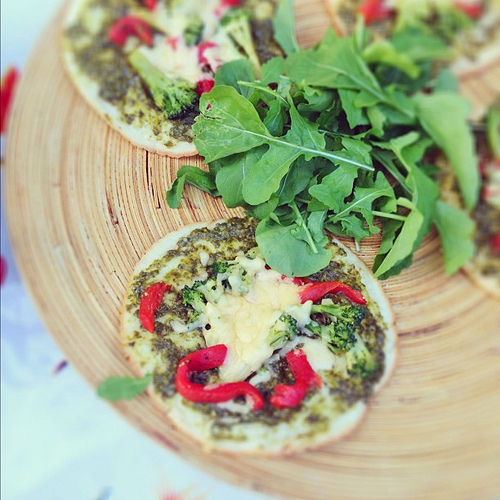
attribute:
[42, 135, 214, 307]
plate — wooden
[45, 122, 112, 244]
line — curved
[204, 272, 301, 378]
cheese — cluster, melted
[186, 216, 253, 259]
broccoli — tiny, crown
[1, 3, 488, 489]
plate — wicker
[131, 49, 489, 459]
food — colorful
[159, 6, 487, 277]
greens — handful, leafy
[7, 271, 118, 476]
table — white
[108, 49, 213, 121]
broccoli — green, peice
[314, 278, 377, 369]
broccoli — green, peice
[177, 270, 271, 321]
broccoli — green, peice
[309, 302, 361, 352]
broccoli — green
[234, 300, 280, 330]
cheese — melted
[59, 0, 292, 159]
pizza — healthy, looking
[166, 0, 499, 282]
arugula — leafy, green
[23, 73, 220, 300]
dish — brown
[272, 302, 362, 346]
broccoli — bits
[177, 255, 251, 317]
broccoli —  bits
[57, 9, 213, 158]
food — round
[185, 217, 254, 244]
seasoning — green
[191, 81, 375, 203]
leaves — yellow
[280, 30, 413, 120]
leaves — yellow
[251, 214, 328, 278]
leaves — yellow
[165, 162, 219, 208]
leaves — yellow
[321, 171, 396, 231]
leaves — yellow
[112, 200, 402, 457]
food — green, red, white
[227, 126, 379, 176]
stem — green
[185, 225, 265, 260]
sauce — green